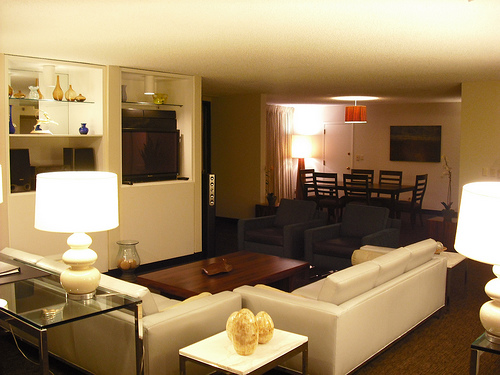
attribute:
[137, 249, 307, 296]
table — wooden, brown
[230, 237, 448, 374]
sofa — white, leather, off white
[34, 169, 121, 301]
lamp — white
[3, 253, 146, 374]
table — glass, clear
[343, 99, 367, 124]
light — red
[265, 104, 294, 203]
curtain — long, white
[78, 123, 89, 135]
vase — small, blue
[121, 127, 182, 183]
television — black, flat screen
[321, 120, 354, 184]
door — closed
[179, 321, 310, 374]
end table — black, white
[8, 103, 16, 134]
bottle — blue